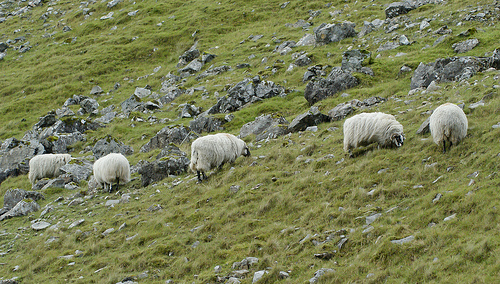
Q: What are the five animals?
A: Sheep.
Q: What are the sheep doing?
A: Grazing.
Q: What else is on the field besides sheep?
A: Rocks.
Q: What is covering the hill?
A: Grass and rocks.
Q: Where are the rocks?
A: On the hill.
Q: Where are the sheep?
A: In a field.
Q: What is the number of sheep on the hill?
A: Five.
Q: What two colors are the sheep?
A: Black and white.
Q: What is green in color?
A: The grass.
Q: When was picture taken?
A: During the day.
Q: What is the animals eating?
A: Grass.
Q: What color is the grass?
A: Green.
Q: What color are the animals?
A: White.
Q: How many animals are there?
A: Five.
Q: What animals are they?
A: Sheep.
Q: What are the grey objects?
A: Rocks.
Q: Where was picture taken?
A: In the hills.